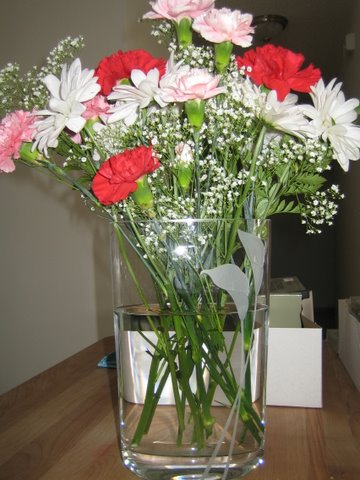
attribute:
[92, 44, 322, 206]
flowers — red, grouped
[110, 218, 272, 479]
vase — half empty, clear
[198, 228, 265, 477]
design — white, etched, stenciled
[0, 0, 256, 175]
flowers — pink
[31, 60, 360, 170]
flowers — white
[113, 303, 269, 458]
water — clear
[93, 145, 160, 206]
flower — red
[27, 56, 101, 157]
flower — white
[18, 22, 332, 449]
stems — green, tall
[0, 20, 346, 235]
flowers — small, white, bunched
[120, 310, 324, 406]
box — white, cardboard, thin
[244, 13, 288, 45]
light — domed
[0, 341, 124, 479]
lines — light colored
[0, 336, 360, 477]
wood — brown, wooden, distinct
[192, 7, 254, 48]
flower — pink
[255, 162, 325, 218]
leaves — green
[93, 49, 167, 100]
carnation — red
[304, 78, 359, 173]
daisy — white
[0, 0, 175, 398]
wall — white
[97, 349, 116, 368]
fabric — blue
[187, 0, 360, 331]
passageway — dark